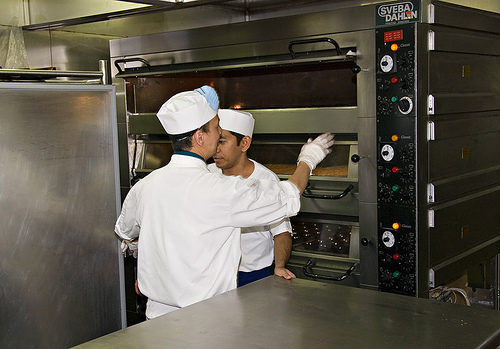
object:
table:
[69, 272, 500, 348]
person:
[199, 107, 297, 280]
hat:
[214, 108, 256, 138]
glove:
[295, 131, 335, 176]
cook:
[129, 90, 359, 182]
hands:
[297, 131, 335, 177]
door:
[1, 81, 127, 346]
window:
[115, 58, 359, 114]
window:
[130, 132, 360, 185]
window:
[288, 212, 361, 259]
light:
[390, 43, 398, 51]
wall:
[255, 107, 320, 135]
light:
[233, 104, 242, 109]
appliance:
[110, 0, 499, 301]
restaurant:
[0, 3, 499, 348]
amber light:
[392, 222, 400, 229]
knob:
[381, 144, 395, 162]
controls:
[376, 25, 417, 299]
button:
[392, 167, 399, 174]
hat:
[155, 85, 220, 135]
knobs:
[377, 23, 417, 295]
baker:
[114, 85, 335, 318]